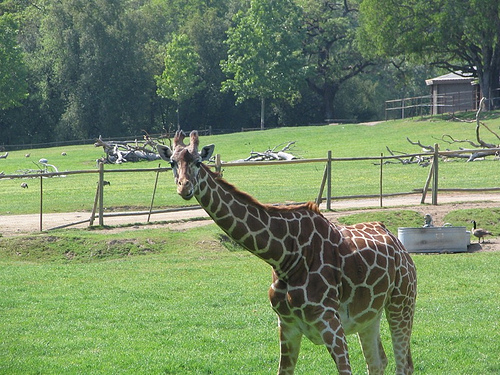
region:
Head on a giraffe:
[148, 124, 223, 221]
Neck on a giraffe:
[167, 152, 297, 264]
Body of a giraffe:
[252, 204, 419, 348]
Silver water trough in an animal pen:
[386, 218, 471, 255]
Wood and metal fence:
[16, 144, 498, 214]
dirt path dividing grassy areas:
[7, 113, 496, 366]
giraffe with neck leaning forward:
[145, 125, 419, 368]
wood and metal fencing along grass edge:
[1, 144, 495, 240]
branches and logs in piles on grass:
[89, 132, 294, 167]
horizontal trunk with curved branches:
[372, 92, 494, 168]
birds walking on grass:
[15, 147, 72, 189]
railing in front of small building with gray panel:
[378, 60, 490, 120]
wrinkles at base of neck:
[263, 223, 313, 298]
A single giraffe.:
[152, 124, 419, 374]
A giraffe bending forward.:
[153, 130, 419, 374]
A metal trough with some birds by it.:
[398, 211, 490, 253]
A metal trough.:
[397, 219, 471, 254]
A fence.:
[3, 143, 498, 240]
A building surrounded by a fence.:
[380, 59, 497, 114]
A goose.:
[470, 216, 493, 248]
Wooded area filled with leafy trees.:
[0, 2, 499, 149]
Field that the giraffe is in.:
[2, 196, 497, 373]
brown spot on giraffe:
[198, 180, 206, 190]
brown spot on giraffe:
[201, 187, 213, 207]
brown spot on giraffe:
[209, 189, 221, 211]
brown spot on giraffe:
[215, 203, 230, 215]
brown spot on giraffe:
[216, 214, 231, 229]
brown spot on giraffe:
[228, 202, 247, 219]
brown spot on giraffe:
[244, 214, 266, 233]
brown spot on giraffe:
[253, 228, 271, 250]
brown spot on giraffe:
[268, 239, 286, 262]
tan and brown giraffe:
[148, 132, 428, 357]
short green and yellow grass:
[114, 311, 131, 330]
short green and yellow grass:
[197, 272, 239, 299]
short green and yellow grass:
[441, 313, 471, 349]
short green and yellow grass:
[427, 270, 465, 302]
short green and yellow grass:
[135, 266, 185, 291]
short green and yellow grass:
[78, 294, 127, 324]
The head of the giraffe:
[150, 128, 217, 203]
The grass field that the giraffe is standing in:
[2, 115, 497, 373]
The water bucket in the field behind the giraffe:
[389, 220, 476, 257]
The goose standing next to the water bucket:
[465, 214, 497, 246]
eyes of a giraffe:
[166, 155, 203, 175]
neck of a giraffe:
[201, 177, 281, 256]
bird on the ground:
[465, 216, 490, 248]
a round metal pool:
[398, 218, 474, 258]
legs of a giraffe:
[271, 308, 414, 373]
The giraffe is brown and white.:
[143, 129, 418, 372]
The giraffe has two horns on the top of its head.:
[173, 131, 201, 148]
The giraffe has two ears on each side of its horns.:
[158, 140, 213, 160]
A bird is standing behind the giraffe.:
[467, 215, 491, 248]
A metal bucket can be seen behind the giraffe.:
[388, 221, 470, 253]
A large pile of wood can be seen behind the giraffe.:
[363, 122, 497, 168]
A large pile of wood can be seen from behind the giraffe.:
[96, 133, 163, 167]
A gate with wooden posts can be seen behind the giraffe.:
[7, 146, 498, 216]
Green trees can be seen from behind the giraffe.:
[4, 48, 499, 129]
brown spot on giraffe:
[347, 283, 373, 318]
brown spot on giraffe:
[197, 187, 210, 208]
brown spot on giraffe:
[215, 185, 233, 202]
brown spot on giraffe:
[215, 200, 230, 220]